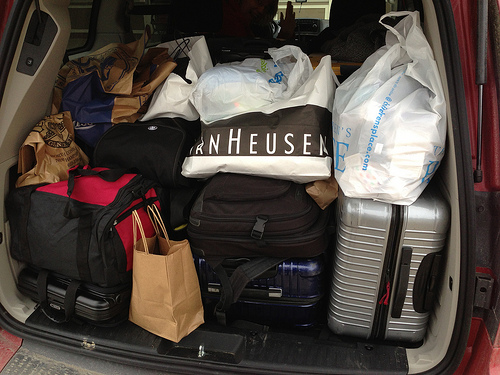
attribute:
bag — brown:
[28, 119, 102, 181]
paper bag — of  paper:
[128, 201, 205, 362]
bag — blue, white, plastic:
[325, 12, 447, 207]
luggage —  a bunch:
[2, 8, 452, 343]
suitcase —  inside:
[195, 255, 323, 333]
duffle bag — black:
[23, 138, 157, 295]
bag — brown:
[106, 224, 230, 356]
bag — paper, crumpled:
[66, 44, 153, 124]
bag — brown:
[100, 197, 223, 333]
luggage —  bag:
[326, 196, 469, 348]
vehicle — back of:
[1, 0, 498, 373]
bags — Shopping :
[40, 44, 422, 365]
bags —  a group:
[116, 205, 212, 343]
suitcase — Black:
[329, 193, 446, 345]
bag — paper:
[112, 202, 221, 347]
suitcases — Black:
[104, 122, 183, 175]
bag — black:
[5, 167, 163, 288]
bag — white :
[191, 52, 336, 187]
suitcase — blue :
[324, 180, 445, 364]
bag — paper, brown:
[121, 198, 208, 342]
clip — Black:
[239, 202, 291, 242]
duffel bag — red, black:
[12, 165, 159, 290]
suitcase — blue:
[184, 257, 336, 333]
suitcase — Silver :
[331, 189, 438, 353]